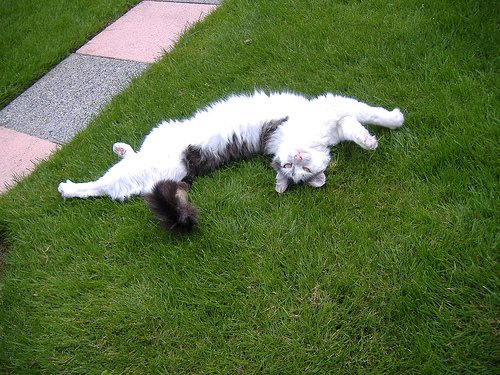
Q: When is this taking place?
A: Daytime.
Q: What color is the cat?
A: Black and white.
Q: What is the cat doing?
A: Stretching.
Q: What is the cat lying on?
A: Grass.